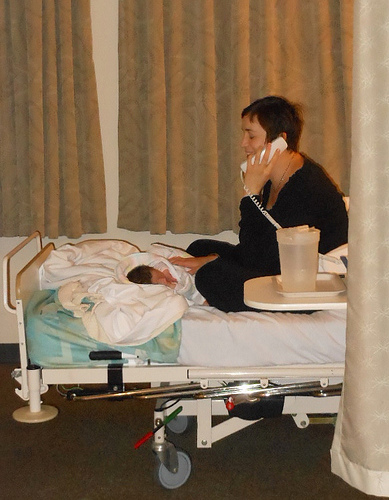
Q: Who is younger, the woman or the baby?
A: The baby is younger than the woman.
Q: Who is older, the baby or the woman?
A: The woman is older than the baby.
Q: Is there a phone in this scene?
A: Yes, there is a phone.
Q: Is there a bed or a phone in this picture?
A: Yes, there is a phone.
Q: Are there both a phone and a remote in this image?
A: No, there is a phone but no remote controls.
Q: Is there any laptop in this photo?
A: No, there are no laptops.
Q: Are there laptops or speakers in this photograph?
A: No, there are no laptops or speakers.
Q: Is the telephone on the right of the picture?
A: Yes, the telephone is on the right of the image.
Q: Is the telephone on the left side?
A: No, the telephone is on the right of the image.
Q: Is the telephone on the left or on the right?
A: The telephone is on the right of the image.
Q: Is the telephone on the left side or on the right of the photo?
A: The telephone is on the right of the image.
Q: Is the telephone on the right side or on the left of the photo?
A: The telephone is on the right of the image.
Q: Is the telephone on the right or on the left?
A: The telephone is on the right of the image.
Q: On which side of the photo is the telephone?
A: The telephone is on the right of the image.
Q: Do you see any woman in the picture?
A: Yes, there is a woman.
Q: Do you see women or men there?
A: Yes, there is a woman.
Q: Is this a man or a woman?
A: This is a woman.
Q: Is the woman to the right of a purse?
A: No, the woman is to the right of the curtain.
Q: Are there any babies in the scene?
A: Yes, there is a baby.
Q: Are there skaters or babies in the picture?
A: Yes, there is a baby.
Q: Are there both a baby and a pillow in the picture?
A: No, there is a baby but no pillows.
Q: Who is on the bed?
A: The baby is on the bed.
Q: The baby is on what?
A: The baby is on the bed.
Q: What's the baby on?
A: The baby is on the bed.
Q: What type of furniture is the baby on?
A: The baby is on the bed.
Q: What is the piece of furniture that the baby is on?
A: The piece of furniture is a bed.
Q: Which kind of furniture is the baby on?
A: The baby is on the bed.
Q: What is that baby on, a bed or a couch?
A: The baby is on a bed.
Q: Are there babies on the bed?
A: Yes, there is a baby on the bed.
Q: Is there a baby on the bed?
A: Yes, there is a baby on the bed.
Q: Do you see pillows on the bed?
A: No, there is a baby on the bed.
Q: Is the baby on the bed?
A: Yes, the baby is on the bed.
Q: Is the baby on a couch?
A: No, the baby is on the bed.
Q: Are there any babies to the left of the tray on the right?
A: Yes, there is a baby to the left of the tray.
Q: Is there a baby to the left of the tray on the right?
A: Yes, there is a baby to the left of the tray.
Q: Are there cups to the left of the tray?
A: No, there is a baby to the left of the tray.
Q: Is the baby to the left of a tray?
A: Yes, the baby is to the left of a tray.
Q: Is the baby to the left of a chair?
A: No, the baby is to the left of a tray.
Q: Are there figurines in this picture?
A: No, there are no figurines.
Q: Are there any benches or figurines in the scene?
A: No, there are no figurines or benches.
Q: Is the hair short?
A: Yes, the hair is short.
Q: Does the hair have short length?
A: Yes, the hair is short.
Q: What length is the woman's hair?
A: The hair is short.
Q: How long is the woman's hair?
A: The hair is short.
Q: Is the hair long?
A: No, the hair is short.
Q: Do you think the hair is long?
A: No, the hair is short.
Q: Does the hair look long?
A: No, the hair is short.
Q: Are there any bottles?
A: No, there are no bottles.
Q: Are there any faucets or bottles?
A: No, there are no bottles or faucets.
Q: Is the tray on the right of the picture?
A: Yes, the tray is on the right of the image.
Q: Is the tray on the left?
A: No, the tray is on the right of the image.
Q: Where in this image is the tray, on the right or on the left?
A: The tray is on the right of the image.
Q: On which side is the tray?
A: The tray is on the right of the image.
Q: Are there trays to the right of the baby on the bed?
A: Yes, there is a tray to the right of the baby.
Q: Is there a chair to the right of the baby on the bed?
A: No, there is a tray to the right of the baby.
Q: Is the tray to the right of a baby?
A: Yes, the tray is to the right of a baby.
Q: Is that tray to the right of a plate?
A: No, the tray is to the right of a baby.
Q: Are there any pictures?
A: No, there are no pictures.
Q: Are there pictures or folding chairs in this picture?
A: No, there are no pictures or folding chairs.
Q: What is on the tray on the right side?
A: The pitcher is on the tray.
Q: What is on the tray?
A: The pitcher is on the tray.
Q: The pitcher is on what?
A: The pitcher is on the tray.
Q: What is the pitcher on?
A: The pitcher is on the tray.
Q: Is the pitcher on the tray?
A: Yes, the pitcher is on the tray.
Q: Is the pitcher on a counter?
A: No, the pitcher is on the tray.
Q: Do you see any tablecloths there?
A: No, there are no tablecloths.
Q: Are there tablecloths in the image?
A: No, there are no tablecloths.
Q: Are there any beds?
A: Yes, there is a bed.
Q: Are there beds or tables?
A: Yes, there is a bed.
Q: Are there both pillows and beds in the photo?
A: No, there is a bed but no pillows.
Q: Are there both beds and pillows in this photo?
A: No, there is a bed but no pillows.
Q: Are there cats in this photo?
A: No, there are no cats.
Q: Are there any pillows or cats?
A: No, there are no cats or pillows.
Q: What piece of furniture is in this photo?
A: The piece of furniture is a bed.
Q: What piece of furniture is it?
A: The piece of furniture is a bed.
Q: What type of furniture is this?
A: That is a bed.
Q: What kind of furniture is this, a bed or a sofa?
A: That is a bed.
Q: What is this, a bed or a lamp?
A: This is a bed.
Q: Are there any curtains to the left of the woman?
A: Yes, there is a curtain to the left of the woman.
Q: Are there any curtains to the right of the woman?
A: No, the curtain is to the left of the woman.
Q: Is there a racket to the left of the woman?
A: No, there is a curtain to the left of the woman.